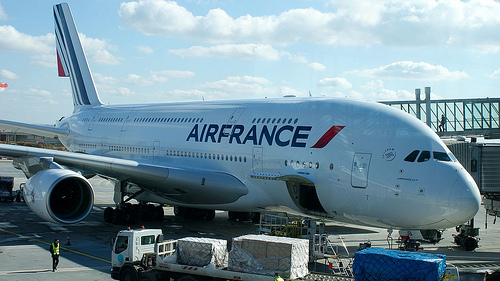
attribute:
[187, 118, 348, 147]
logo — red, blue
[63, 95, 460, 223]
side — plane's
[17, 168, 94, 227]
engine — airplane's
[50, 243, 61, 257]
vest — orange, yellow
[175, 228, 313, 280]
cargo — airplane's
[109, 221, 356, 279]
truck — flatbed, hauling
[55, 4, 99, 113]
tail — airplane's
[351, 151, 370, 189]
door — closed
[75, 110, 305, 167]
group — windows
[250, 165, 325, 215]
cargo door — open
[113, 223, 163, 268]
cab — white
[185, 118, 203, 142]
letter — blue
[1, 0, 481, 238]
airplane — sitting, white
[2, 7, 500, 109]
clouds — white, fluffy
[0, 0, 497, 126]
sky — blue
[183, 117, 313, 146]
writing — blue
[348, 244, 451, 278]
luggage carrier — covered